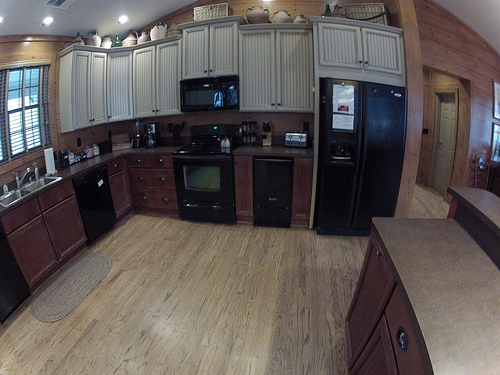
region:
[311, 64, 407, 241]
Double door black refridgerator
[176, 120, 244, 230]
Black stove in a kitchen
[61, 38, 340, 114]
Grey cabinets in a kitchen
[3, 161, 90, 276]
Standard metal kitchen sink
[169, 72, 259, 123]
Black microwave stored above the stove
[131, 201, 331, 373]
Light hard wood flooring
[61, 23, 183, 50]
Decorative white pots in the kitchen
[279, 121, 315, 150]
Stainless steel toaster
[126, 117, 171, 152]
Coffe pot sitting on the kitchen counter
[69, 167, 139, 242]
Black dishwasher in the kitchen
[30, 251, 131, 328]
grey map laying on floor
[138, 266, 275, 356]
light wooden flooring in kitchen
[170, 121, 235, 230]
black metal stove in kitchen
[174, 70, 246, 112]
black microwave above stove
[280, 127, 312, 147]
silver metal toaster on counter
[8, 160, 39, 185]
silver faucet on kitchen sink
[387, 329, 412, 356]
silver metal handle on kitchen drawers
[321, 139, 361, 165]
ice dispenser on front of fridge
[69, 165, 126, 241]
black dishwasher in kitchen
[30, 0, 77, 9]
white air vent in kitchen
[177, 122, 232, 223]
Black stove in kitchen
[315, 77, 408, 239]
Black refrigerator in kitchen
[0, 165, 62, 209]
Silver sink in kitchen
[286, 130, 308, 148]
Chrome toaster on kitchen counter.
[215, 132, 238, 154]
Steel colored kettle on stove.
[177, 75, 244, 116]
Black microwave hanging from cabinets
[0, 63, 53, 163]
Windows with shades above sink.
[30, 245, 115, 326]
Beige colored rug on kitchen floor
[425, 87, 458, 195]
Brown closed door outside of kitchen.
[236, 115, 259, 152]
Spice rack on top kitchen counter.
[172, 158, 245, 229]
the stove is black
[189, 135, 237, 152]
kettle is on stove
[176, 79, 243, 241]
microwave above the stove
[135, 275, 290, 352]
floors are made of wood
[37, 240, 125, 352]
rug is on floor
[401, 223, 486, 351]
couters are brownish gray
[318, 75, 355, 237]
bulletin on the fridge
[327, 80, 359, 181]
icemaker under the bulletin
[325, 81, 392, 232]
the fridge is black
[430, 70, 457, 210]
the door is closed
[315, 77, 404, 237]
a black refrigerator freezer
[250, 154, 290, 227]
a black trash compactor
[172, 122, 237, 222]
a black stove and oven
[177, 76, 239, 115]
an overhead mounted black microwave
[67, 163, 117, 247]
a black dishwasher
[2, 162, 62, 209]
a brushed aluminum sink basin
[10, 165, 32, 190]
a chrome sink faucet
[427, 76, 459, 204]
a closed door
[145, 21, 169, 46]
a white decorative vase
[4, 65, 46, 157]
a window with venetian blinds